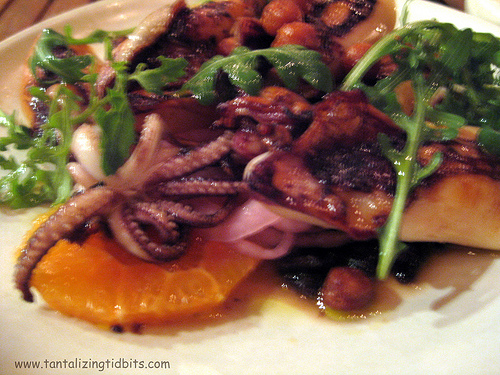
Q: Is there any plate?
A: Yes, there is a plate.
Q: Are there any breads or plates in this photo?
A: Yes, there is a plate.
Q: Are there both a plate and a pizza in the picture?
A: No, there is a plate but no pizzas.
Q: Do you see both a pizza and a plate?
A: No, there is a plate but no pizzas.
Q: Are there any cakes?
A: No, there are no cakes.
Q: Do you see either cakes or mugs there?
A: No, there are no cakes or mugs.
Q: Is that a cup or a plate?
A: That is a plate.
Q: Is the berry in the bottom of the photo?
A: Yes, the berry is in the bottom of the image.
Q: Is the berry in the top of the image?
A: No, the berry is in the bottom of the image.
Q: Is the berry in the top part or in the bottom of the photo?
A: The berry is in the bottom of the image.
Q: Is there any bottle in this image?
A: No, there are no bottles.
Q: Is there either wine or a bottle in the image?
A: No, there are no bottles or wine.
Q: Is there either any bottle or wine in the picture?
A: No, there are no bottles or wine.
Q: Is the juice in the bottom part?
A: Yes, the juice is in the bottom of the image.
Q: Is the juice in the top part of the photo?
A: No, the juice is in the bottom of the image.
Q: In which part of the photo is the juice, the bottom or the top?
A: The juice is in the bottom of the image.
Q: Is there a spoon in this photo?
A: No, there are no spoons.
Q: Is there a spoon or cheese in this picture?
A: No, there are no spoons or cheese.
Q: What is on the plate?
A: The sauce is on the plate.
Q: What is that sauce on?
A: The sauce is on the plate.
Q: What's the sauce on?
A: The sauce is on the plate.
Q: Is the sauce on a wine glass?
A: No, the sauce is on the plate.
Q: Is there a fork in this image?
A: No, there are no forks.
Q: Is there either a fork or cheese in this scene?
A: No, there are no forks or cheese.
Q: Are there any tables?
A: Yes, there is a table.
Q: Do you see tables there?
A: Yes, there is a table.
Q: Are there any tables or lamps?
A: Yes, there is a table.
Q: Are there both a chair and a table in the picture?
A: No, there is a table but no chairs.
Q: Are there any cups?
A: No, there are no cups.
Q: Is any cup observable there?
A: No, there are no cups.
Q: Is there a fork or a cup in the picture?
A: No, there are no cups or forks.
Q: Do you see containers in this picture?
A: No, there are no containers.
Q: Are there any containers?
A: No, there are no containers.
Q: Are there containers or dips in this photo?
A: No, there are no containers or dips.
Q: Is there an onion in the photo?
A: Yes, there is an onion.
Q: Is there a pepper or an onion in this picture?
A: Yes, there is an onion.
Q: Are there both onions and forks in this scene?
A: No, there is an onion but no forks.